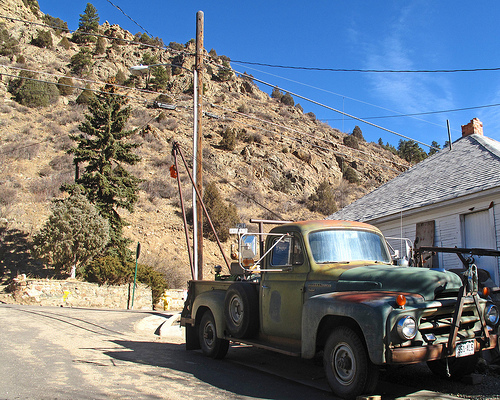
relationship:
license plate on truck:
[456, 339, 476, 357] [180, 218, 499, 399]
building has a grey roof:
[323, 118, 500, 289] [324, 117, 500, 222]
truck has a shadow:
[180, 218, 499, 399] [103, 340, 499, 400]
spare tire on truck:
[224, 282, 259, 338] [180, 218, 499, 399]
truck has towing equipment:
[180, 218, 499, 399] [171, 142, 258, 282]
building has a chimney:
[323, 118, 500, 289] [460, 117, 482, 138]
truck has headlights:
[180, 218, 499, 399] [396, 304, 500, 340]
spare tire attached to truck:
[224, 282, 259, 338] [180, 218, 499, 399]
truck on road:
[180, 218, 499, 399] [0, 303, 397, 400]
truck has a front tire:
[180, 218, 499, 399] [322, 326, 379, 398]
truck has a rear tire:
[180, 218, 499, 399] [198, 309, 229, 359]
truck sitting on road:
[180, 218, 499, 399] [0, 303, 397, 400]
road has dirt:
[0, 303, 397, 400] [0, 303, 364, 399]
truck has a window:
[180, 218, 499, 399] [271, 233, 304, 268]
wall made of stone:
[0, 276, 187, 312] [1, 276, 189, 313]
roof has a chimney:
[324, 117, 500, 222] [460, 117, 482, 138]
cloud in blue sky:
[347, 1, 500, 136] [35, 1, 500, 154]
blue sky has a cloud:
[35, 1, 500, 154] [347, 1, 500, 136]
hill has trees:
[0, 1, 425, 305] [0, 0, 455, 311]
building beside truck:
[323, 118, 500, 289] [180, 218, 499, 399]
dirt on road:
[0, 303, 364, 399] [0, 303, 397, 400]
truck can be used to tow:
[180, 218, 499, 399] [171, 142, 258, 282]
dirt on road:
[0, 303, 364, 399] [0, 303, 460, 398]